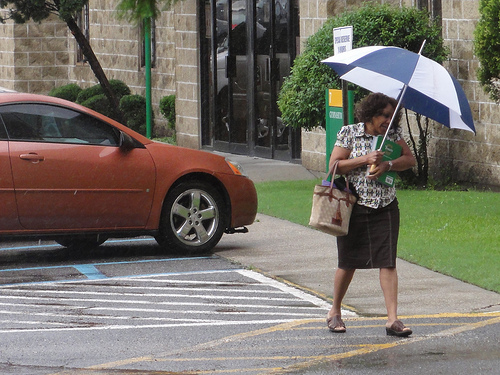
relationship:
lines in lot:
[81, 308, 496, 372] [4, 237, 497, 371]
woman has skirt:
[327, 93, 415, 334] [337, 192, 410, 269]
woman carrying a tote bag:
[327, 93, 415, 334] [306, 162, 354, 230]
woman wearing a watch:
[327, 93, 415, 334] [384, 160, 399, 170]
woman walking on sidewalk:
[327, 93, 415, 334] [308, 273, 466, 373]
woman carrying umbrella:
[327, 93, 415, 334] [315, 30, 479, 170]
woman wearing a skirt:
[327, 93, 415, 334] [320, 188, 418, 270]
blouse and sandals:
[335, 139, 401, 235] [316, 308, 413, 333]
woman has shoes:
[327, 93, 415, 334] [323, 311, 412, 337]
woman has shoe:
[327, 93, 415, 334] [328, 313, 348, 331]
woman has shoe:
[327, 93, 415, 334] [388, 318, 412, 337]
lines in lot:
[2, 262, 359, 333] [3, 208, 497, 368]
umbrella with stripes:
[313, 37, 478, 143] [376, 41, 451, 107]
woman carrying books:
[327, 93, 415, 334] [370, 137, 405, 161]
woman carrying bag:
[327, 93, 415, 334] [308, 180, 355, 234]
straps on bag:
[328, 161, 350, 194] [306, 159, 356, 239]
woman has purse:
[327, 93, 415, 334] [306, 159, 358, 237]